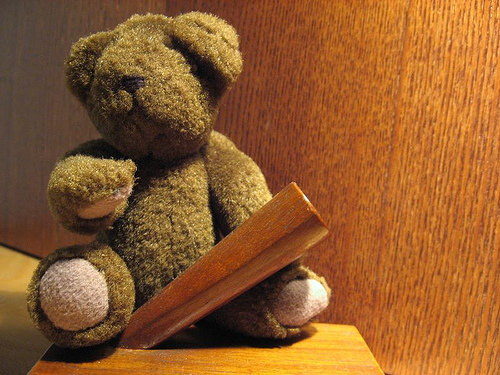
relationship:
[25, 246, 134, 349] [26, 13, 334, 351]
foot on bear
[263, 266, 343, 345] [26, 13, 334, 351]
foot on bear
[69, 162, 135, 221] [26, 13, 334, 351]
paw on bear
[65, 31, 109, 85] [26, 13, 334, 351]
ear on bear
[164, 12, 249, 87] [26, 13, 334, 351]
ear on bear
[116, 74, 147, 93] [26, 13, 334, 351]
nose on bear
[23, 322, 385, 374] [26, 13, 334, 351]
stand below bear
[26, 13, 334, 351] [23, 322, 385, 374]
bear on stand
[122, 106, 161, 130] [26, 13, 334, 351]
mouth on bear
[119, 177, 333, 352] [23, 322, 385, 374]
wood on stand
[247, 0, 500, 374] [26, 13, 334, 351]
wall behind bear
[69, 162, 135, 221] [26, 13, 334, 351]
paw of bear